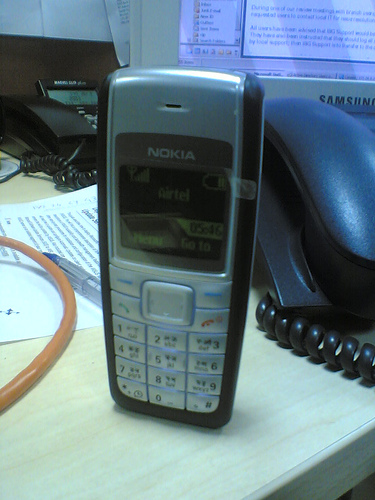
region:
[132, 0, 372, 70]
samsung computer monitor in background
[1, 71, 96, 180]
black push button phone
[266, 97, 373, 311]
black phone in front of monitor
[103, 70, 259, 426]
Nokia cell phone standing up on table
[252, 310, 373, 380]
telephone chord of black phonr in front of monitor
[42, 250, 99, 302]
blue ball point pen behind nakia cell phone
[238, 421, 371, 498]
edge of white table with everything on it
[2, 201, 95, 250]
notes on white paper under ball point pen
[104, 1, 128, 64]
paper tacted to the wall behind samsung monitor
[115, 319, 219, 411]
buttons on Nokia cellpone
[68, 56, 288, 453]
This is a mobile phone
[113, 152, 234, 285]
This is a mobile phone screen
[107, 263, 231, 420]
This is a mobile phone buttons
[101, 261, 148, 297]
A mobile phone button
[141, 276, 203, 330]
A mobile phone button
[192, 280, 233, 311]
A mobile phone button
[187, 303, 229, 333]
A mobile phone button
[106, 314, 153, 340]
A mobile phone button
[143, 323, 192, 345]
A mobile phone button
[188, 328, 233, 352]
A mobile phone button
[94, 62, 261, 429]
a nokia cell phone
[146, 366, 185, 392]
the number 8 on the phone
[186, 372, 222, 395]
the number 9 on the phone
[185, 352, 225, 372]
the number 6 on the phone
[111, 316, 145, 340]
the number 1 on the phone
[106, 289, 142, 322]
the call button on the phone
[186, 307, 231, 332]
the end button on the phone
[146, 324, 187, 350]
the number 2 on the phone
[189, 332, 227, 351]
the number 3 on the phone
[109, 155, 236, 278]
the screen of the phone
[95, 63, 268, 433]
Nokia cell phone with black casing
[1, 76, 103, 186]
a desk phone black in color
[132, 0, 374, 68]
a computer monitor turned on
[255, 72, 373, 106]
a samsung computer monitor logo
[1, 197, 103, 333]
a paper with a pen on top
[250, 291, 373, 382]
black phone cord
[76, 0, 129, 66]
paper attached to wall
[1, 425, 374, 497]
light colored desk top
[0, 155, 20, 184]
a light colored dish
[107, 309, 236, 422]
number pad on cell phone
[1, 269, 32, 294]
this is the paper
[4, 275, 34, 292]
the paper is white in color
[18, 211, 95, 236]
these are some writings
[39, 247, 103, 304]
this is a pen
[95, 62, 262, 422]
this is a mobile phone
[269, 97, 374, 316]
this is a telephone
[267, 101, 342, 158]
the telephone is black in color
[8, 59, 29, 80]
this is a wall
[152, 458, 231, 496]
the table is white in color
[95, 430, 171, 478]
the table is wooden